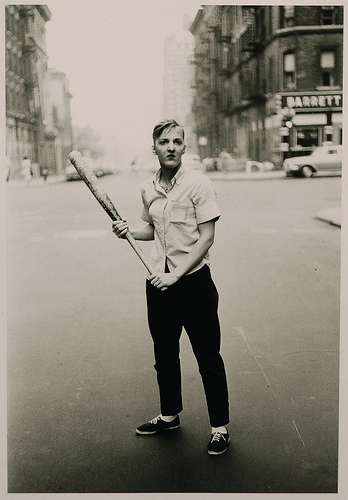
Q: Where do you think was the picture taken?
A: It was taken at the street.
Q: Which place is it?
A: It is a street.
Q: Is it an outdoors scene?
A: Yes, it is outdoors.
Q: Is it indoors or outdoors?
A: It is outdoors.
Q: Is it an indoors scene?
A: No, it is outdoors.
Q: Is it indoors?
A: No, it is outdoors.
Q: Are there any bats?
A: Yes, there is a bat.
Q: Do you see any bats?
A: Yes, there is a bat.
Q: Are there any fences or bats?
A: Yes, there is a bat.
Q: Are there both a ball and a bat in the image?
A: No, there is a bat but no balls.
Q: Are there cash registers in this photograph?
A: No, there are no cash registers.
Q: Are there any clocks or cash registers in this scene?
A: No, there are no cash registers or clocks.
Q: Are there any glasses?
A: No, there are no glasses.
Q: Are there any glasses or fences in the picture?
A: No, there are no glasses or fences.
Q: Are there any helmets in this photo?
A: No, there are no helmets.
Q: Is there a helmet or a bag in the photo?
A: No, there are no helmets or bags.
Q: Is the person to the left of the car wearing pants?
A: Yes, the person is wearing pants.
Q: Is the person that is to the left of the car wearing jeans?
A: No, the person is wearing pants.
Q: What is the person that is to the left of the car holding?
A: The person is holding the bat.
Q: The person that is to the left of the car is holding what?
A: The person is holding the bat.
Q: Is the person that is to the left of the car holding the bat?
A: Yes, the person is holding the bat.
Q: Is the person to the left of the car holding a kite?
A: No, the person is holding the bat.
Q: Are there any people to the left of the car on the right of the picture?
A: Yes, there is a person to the left of the car.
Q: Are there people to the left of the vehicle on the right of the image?
A: Yes, there is a person to the left of the car.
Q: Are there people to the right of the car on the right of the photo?
A: No, the person is to the left of the car.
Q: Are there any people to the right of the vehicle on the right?
A: No, the person is to the left of the car.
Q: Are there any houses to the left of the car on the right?
A: No, there is a person to the left of the car.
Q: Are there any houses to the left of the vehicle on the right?
A: No, there is a person to the left of the car.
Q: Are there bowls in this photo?
A: No, there are no bowls.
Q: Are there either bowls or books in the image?
A: No, there are no bowls or books.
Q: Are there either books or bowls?
A: No, there are no bowls or books.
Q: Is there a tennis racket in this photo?
A: No, there are no rackets.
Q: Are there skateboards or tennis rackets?
A: No, there are no tennis rackets or skateboards.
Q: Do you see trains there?
A: No, there are no trains.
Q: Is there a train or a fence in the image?
A: No, there are no trains or fences.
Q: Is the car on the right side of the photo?
A: Yes, the car is on the right of the image.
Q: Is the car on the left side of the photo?
A: No, the car is on the right of the image.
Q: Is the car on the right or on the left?
A: The car is on the right of the image.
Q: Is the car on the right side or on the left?
A: The car is on the right of the image.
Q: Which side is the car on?
A: The car is on the right of the image.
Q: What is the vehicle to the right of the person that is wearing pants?
A: The vehicle is a car.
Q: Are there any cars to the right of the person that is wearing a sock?
A: Yes, there is a car to the right of the person.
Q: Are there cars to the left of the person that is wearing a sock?
A: No, the car is to the right of the person.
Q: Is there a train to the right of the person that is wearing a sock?
A: No, there is a car to the right of the person.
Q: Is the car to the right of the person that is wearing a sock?
A: Yes, the car is to the right of the person.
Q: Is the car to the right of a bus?
A: No, the car is to the right of the person.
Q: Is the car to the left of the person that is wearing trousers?
A: No, the car is to the right of the person.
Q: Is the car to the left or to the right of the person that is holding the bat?
A: The car is to the right of the person.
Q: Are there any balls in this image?
A: No, there are no balls.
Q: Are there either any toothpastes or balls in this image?
A: No, there are no balls or toothpastes.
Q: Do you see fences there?
A: No, there are no fences.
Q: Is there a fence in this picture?
A: No, there are no fences.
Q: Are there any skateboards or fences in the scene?
A: No, there are no fences or skateboards.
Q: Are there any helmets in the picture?
A: No, there are no helmets.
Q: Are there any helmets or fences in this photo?
A: No, there are no helmets or fences.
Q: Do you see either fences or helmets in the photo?
A: No, there are no helmets or fences.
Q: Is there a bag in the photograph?
A: No, there are no bags.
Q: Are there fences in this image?
A: No, there are no fences.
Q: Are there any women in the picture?
A: Yes, there is a woman.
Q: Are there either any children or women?
A: Yes, there is a woman.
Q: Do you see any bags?
A: No, there are no bags.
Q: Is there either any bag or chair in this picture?
A: No, there are no bags or chairs.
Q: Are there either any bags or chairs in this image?
A: No, there are no bags or chairs.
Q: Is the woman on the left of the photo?
A: Yes, the woman is on the left of the image.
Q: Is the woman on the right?
A: No, the woman is on the left of the image.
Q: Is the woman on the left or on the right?
A: The woman is on the left of the image.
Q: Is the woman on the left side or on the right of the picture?
A: The woman is on the left of the image.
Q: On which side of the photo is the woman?
A: The woman is on the left of the image.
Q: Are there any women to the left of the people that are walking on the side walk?
A: Yes, there is a woman to the left of the people.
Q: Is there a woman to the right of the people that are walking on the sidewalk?
A: No, the woman is to the left of the people.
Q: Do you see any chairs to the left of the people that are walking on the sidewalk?
A: No, there is a woman to the left of the people.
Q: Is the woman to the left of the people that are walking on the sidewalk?
A: Yes, the woman is to the left of the people.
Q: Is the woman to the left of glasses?
A: No, the woman is to the left of the people.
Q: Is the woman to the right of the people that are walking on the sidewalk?
A: No, the woman is to the left of the people.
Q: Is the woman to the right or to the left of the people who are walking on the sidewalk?
A: The woman is to the left of the people.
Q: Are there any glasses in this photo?
A: No, there are no glasses.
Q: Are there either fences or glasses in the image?
A: No, there are no glasses or fences.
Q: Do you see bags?
A: No, there are no bags.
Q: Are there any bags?
A: No, there are no bags.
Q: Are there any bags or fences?
A: No, there are no bags or fences.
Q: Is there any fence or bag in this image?
A: No, there are no bags or fences.